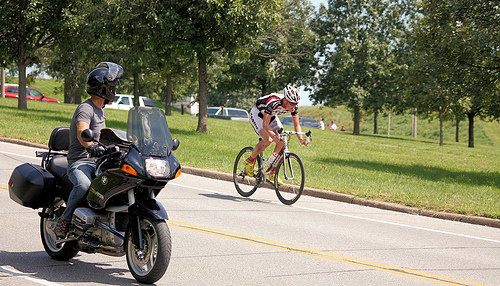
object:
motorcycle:
[5, 105, 180, 284]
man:
[52, 57, 126, 238]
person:
[245, 86, 310, 185]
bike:
[232, 125, 314, 211]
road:
[237, 222, 461, 284]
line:
[204, 226, 331, 263]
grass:
[355, 147, 499, 197]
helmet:
[73, 61, 133, 100]